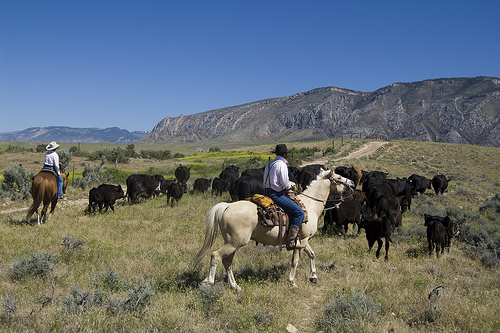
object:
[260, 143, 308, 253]
man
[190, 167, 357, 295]
horse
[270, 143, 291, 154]
hat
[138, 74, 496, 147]
mountain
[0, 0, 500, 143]
background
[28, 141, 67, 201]
man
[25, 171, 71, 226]
horse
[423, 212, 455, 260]
animals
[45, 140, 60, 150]
hat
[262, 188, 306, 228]
jeans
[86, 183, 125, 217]
cattle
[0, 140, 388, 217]
road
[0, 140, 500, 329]
field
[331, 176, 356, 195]
bridle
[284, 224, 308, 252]
boots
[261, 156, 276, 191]
suspenders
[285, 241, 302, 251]
stirrup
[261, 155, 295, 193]
shirt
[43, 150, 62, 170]
shirt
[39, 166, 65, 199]
jeans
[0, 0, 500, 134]
sky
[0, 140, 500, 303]
grass